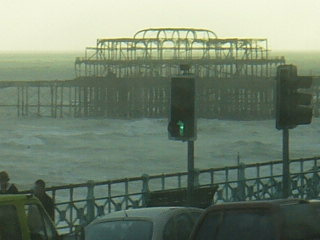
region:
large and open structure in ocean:
[32, 18, 311, 148]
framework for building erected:
[40, 22, 276, 131]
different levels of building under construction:
[73, 20, 284, 133]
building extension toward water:
[4, 22, 127, 115]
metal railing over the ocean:
[48, 144, 294, 227]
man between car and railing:
[4, 166, 57, 216]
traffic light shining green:
[155, 57, 203, 193]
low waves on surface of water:
[24, 113, 157, 170]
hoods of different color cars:
[89, 188, 305, 229]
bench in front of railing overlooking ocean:
[104, 157, 228, 210]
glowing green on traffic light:
[169, 114, 188, 140]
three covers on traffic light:
[292, 68, 315, 129]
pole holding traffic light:
[273, 133, 302, 192]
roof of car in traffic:
[114, 193, 196, 233]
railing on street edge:
[79, 171, 143, 203]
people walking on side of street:
[0, 156, 59, 203]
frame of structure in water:
[77, 43, 163, 111]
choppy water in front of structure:
[54, 119, 139, 172]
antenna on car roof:
[114, 198, 139, 220]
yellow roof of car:
[2, 188, 37, 214]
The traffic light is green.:
[160, 113, 196, 143]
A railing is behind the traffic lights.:
[0, 150, 318, 234]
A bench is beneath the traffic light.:
[136, 177, 224, 219]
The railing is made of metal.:
[0, 146, 318, 236]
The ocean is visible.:
[0, 83, 319, 195]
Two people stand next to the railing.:
[1, 159, 65, 231]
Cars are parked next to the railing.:
[0, 167, 315, 238]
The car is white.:
[62, 195, 206, 238]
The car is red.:
[191, 190, 318, 239]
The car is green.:
[0, 190, 65, 238]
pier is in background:
[6, 14, 314, 152]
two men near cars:
[0, 166, 71, 235]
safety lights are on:
[154, 53, 319, 175]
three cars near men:
[4, 182, 318, 239]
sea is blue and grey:
[4, 115, 286, 171]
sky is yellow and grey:
[2, 13, 317, 69]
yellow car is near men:
[0, 185, 59, 237]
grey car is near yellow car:
[64, 196, 201, 236]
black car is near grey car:
[196, 187, 309, 239]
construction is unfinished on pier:
[66, 23, 319, 124]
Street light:
[112, 104, 200, 166]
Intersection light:
[149, 32, 303, 129]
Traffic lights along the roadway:
[86, 43, 302, 142]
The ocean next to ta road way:
[49, 73, 130, 154]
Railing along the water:
[96, 177, 179, 204]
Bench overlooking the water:
[144, 180, 292, 219]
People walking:
[1, 169, 101, 226]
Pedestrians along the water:
[6, 140, 78, 226]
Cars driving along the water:
[71, 90, 248, 239]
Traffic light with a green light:
[146, 50, 218, 205]